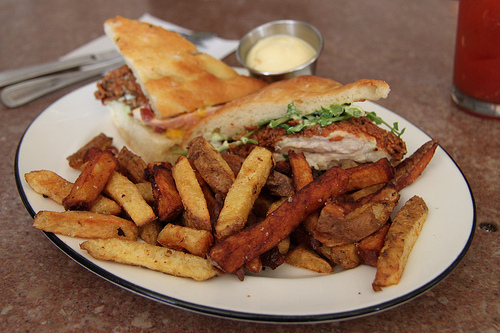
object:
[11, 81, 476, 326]
plate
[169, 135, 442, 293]
cut up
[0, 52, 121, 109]
utensils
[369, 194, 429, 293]
fry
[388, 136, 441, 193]
fry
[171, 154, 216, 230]
fry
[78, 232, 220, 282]
fry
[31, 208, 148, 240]
fry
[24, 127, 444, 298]
fries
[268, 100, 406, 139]
lettuce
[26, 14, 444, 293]
food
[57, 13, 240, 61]
napkin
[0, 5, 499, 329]
table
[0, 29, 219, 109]
silverware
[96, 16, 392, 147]
sandwhich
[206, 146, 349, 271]
potatoe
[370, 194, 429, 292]
potatoe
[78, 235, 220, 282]
potatoe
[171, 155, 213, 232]
potatoe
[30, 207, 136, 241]
potatoe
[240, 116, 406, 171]
chicken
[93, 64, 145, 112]
chicken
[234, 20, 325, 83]
cup